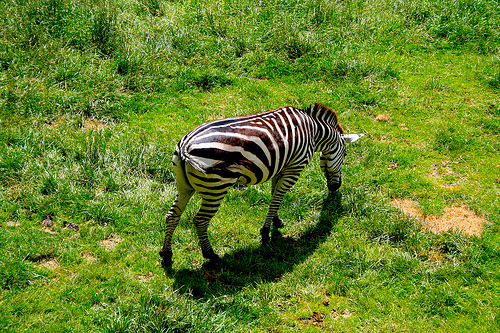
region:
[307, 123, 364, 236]
the zebra is eating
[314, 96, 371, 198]
the zebra is eating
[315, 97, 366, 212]
the zebra is eating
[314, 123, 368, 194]
the zebra is eating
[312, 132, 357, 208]
zebra is eating grass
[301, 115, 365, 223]
zebra is eating grass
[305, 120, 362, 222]
zebra is eating grass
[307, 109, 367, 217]
zebra is eating grass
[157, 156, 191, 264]
the black and white striped leg of the zebra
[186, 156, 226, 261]
the black and white striped leg of the zebra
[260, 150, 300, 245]
the black and white striped leg of the zebra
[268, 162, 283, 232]
the black and white striped leg of the zebra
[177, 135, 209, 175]
the black and white striped tail of the zebra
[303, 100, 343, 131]
the black and white mane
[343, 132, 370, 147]
the white ear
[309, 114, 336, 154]
the striped neck of the zebra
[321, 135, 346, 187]
the head of the zebra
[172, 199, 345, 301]
the shadow on the ground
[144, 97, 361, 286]
zebra eating green grass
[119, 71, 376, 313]
zebra eating green grass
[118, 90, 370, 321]
zebra eating green grass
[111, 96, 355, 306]
zebra eating green grass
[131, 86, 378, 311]
zebra eating green grass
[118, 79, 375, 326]
zebra eating green grass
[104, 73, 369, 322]
zebra eating green grass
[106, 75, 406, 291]
zebra eating green grass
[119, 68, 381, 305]
zebra eating green grass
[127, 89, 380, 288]
zebra standing on the grass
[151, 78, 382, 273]
black and white zebra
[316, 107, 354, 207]
head bent down to the ground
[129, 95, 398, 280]
zebra grazing in the grass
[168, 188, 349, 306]
shadow from the zebra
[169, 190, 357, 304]
shadow on the ground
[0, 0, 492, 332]
green grass on the ground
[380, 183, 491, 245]
patch of dirt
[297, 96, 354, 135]
hair along the neck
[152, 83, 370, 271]
black and white stripes on the body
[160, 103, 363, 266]
Black and white zebra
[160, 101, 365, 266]
Zebra grazing on grass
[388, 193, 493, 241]
Patch of dead dried grass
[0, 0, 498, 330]
Large field of grass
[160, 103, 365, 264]
Zebra standing in a field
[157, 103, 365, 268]
Zebra standing on the grass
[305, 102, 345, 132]
Black white and brown zebra mane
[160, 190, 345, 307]
Shadow on the grass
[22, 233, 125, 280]
Three patches of dead grass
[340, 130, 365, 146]
Pointy zebra ear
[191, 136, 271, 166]
zebra has a stripe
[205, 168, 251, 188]
zebra has a stripe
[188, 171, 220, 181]
zebra has a stripe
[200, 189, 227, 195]
zebra has a stripe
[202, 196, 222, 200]
zebra has a stripe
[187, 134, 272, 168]
zebra has a stripe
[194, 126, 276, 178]
zebra has a stripe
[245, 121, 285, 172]
zebra has a stripe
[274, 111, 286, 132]
zebra has a stripe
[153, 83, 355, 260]
zebra grazing in the field